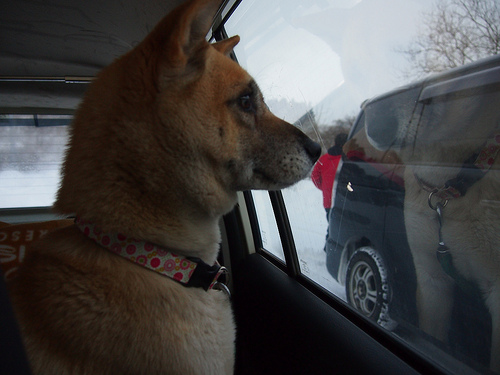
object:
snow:
[334, 239, 398, 330]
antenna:
[0, 110, 76, 123]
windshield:
[0, 115, 70, 218]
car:
[0, 0, 500, 375]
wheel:
[343, 246, 403, 331]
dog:
[2, 4, 321, 375]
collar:
[61, 213, 235, 294]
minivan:
[326, 57, 499, 366]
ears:
[178, 13, 226, 84]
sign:
[0, 217, 72, 273]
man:
[312, 130, 348, 252]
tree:
[395, 3, 497, 75]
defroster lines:
[0, 115, 67, 207]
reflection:
[401, 58, 500, 373]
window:
[213, 0, 497, 373]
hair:
[54, 0, 321, 220]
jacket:
[313, 147, 342, 209]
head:
[68, 1, 321, 233]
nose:
[272, 114, 321, 161]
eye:
[228, 80, 262, 119]